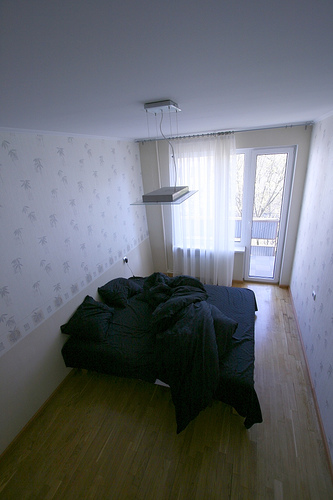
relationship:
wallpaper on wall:
[0, 128, 151, 358] [0, 126, 155, 462]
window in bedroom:
[169, 148, 250, 247] [0, 0, 332, 499]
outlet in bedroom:
[122, 255, 130, 265] [0, 0, 332, 499]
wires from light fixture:
[144, 107, 185, 193] [130, 98, 199, 206]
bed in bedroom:
[62, 276, 263, 428] [0, 0, 332, 499]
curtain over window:
[168, 131, 236, 288] [169, 148, 250, 247]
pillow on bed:
[60, 296, 117, 340] [62, 276, 263, 428]